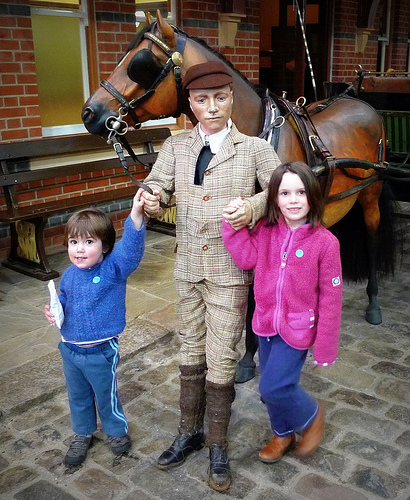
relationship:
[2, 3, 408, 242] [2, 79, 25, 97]
building made of brick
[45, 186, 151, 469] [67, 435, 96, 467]
boy has shoe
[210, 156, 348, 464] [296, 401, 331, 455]
children has shoe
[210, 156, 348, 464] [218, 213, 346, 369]
children has jacket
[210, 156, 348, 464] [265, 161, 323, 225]
children has head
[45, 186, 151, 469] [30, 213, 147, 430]
boy wearing blue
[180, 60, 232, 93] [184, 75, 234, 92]
hat has bill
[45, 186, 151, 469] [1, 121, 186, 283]
boy in front of bench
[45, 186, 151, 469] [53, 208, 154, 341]
boy wearing sweater